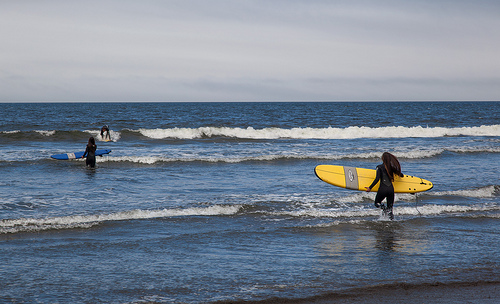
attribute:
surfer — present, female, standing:
[367, 153, 400, 220]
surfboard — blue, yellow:
[51, 148, 113, 161]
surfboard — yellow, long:
[314, 163, 434, 196]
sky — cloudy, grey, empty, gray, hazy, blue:
[2, 2, 494, 101]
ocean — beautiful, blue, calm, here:
[2, 105, 499, 276]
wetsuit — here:
[371, 167, 401, 208]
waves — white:
[140, 119, 496, 145]